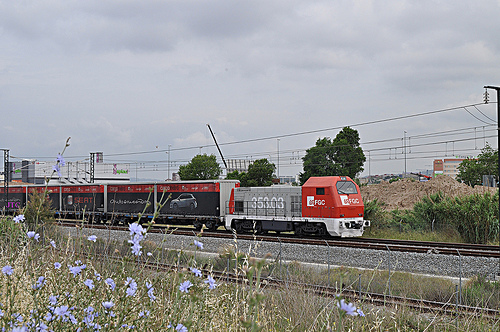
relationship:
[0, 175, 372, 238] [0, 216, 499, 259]
train on tracks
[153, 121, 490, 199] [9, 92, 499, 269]
trees in background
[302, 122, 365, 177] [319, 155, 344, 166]
trees have leaves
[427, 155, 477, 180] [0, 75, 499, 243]
building in background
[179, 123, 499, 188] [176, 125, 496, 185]
leaves on trees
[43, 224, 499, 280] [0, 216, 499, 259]
rocks beside tracks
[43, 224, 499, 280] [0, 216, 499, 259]
rocks surrounding tracks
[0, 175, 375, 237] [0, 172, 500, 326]
train moving through countryside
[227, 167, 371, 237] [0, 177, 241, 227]
locomotive on train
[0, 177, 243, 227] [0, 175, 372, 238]
boxcars on train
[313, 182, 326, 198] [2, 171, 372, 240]
window on freight train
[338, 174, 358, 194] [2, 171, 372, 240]
window on freight train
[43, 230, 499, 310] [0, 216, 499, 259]
grass growing beside tracks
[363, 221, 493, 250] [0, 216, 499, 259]
grass growing beside tracks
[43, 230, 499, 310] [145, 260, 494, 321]
grass growing beside tracks